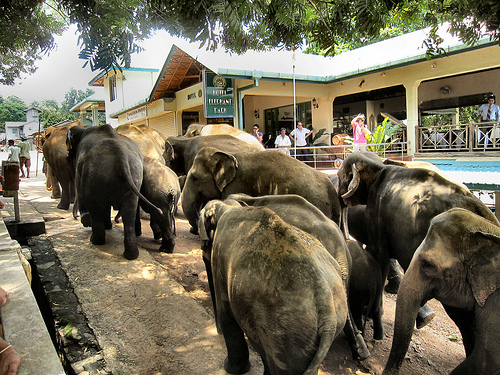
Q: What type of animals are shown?
A: Elephants.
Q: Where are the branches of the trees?
A: Above the elephants.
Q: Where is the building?
A: To the right of the elephants.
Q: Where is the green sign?
A: On the building.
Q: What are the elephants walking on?
A: Gravel.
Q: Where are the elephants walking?
A: In the road.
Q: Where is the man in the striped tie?
A: On the platform.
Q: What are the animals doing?
A: Walking.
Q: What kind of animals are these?
A: Elephants.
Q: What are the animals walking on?
A: The road.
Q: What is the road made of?
A: Dirt.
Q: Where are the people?
A: In the back.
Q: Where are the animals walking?
A: Away from the camera.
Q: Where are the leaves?
A: Above the animals.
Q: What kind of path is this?
A: Dirt.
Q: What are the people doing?
A: Watching the elephats.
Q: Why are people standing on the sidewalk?
A: To watch elephants.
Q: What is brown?
A: Elephant.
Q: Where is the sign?
A: Above the elephants.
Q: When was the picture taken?
A: Daytime.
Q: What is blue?
A: Sky.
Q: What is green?
A: Trees.